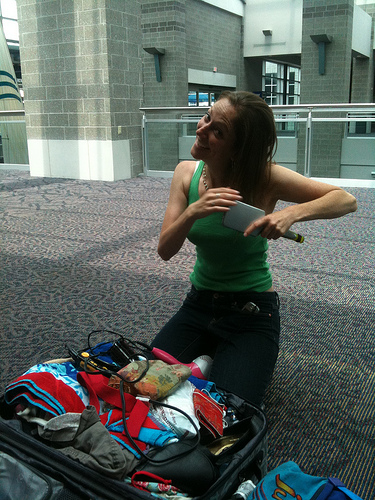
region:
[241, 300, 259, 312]
a cell phone sticking out of a pocket on a pair of jeans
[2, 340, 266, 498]
a black suitcase filled with clothes and personal items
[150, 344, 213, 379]
a pink hair dryer sticking out of a suitcase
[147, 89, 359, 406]
a women in a green top kneeling down and brushing her hair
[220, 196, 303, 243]
a gray hair brush being used by a woman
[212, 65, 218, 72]
an exit sign that is attached to a wall above a doorway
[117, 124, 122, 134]
an electrical outlet attached to a wall that is made of brick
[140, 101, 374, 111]
a metal handrail positioned above a glass guard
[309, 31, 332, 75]
a large black light fixture found attached high on a wall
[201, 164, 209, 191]
a gold colored necklace being worn by a woman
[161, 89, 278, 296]
Woman brushing her hair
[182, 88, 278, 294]
Woman wearing green tank top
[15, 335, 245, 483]
Open suitcase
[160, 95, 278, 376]
woman wearing blue jeans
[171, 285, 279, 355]
Cell phone in pocket of blue jeans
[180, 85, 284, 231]
Woman using a paddle brush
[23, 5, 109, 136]
Column has gray bricks and white mortar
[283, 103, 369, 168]
Glass and steel dividers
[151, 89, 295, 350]
Woman sitting on ground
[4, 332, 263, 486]
Full, disheveled suitcase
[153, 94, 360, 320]
a woman combing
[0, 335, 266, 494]
a suitcase full of clothes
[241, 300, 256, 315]
a smartphone in the pocket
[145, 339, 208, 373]
a red and gray blower between her legs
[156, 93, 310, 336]
a woman smiling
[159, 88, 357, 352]
a skinny woman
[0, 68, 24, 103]
dark greeen patterns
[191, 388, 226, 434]
a red wallet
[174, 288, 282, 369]
a dark blue jeans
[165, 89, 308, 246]
a woman brushing her hair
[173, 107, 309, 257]
a woman holding a brush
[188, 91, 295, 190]
a woman with brown hair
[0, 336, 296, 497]
a open suitcase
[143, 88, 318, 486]
a woman on her knees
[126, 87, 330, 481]
a woman on the floor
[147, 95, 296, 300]
a woman wearing a green shirt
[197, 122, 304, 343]
a woman with a cell phone in her pocket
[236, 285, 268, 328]
a silver cell phone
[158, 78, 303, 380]
a woman wearing black jeans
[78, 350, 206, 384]
pink and silver hair dryer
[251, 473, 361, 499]
blue and yellow pack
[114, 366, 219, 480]
black wire on top of clothes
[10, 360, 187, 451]
clothes folded in a suitcase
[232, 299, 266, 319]
silver and black cellphone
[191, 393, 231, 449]
red and white package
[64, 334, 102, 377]
black and yellow radio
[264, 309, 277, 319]
silver button on pants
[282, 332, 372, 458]
red green and tan carpewt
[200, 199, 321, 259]
silver and yellow hair brush